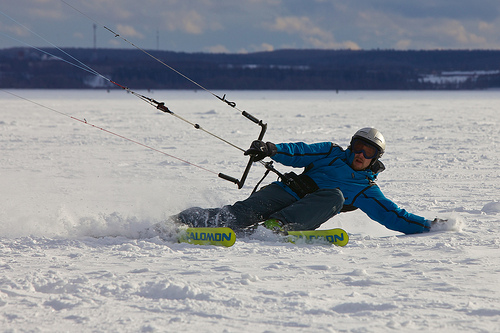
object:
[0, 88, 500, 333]
snow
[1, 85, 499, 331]
hill side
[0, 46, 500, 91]
mountains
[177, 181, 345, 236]
pants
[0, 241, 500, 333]
ground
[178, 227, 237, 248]
board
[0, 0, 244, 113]
rope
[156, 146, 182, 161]
part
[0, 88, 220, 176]
rope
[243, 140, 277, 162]
glove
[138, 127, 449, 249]
guy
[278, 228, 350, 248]
ski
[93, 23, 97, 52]
pole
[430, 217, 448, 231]
left hand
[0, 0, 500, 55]
sky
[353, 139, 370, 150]
shadow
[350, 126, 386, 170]
helmet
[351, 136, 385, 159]
goggles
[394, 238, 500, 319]
surface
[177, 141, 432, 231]
coat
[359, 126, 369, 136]
part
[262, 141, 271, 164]
part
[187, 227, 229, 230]
edge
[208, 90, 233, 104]
edge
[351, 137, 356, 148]
edge